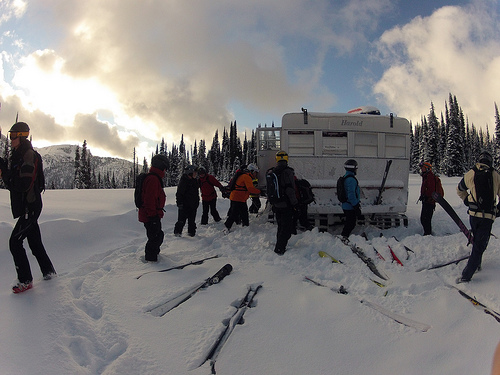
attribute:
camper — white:
[253, 106, 418, 230]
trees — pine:
[71, 92, 499, 190]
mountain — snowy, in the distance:
[22, 127, 177, 197]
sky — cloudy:
[6, 4, 498, 189]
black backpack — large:
[474, 168, 493, 208]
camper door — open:
[249, 111, 338, 233]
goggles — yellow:
[7, 133, 22, 138]